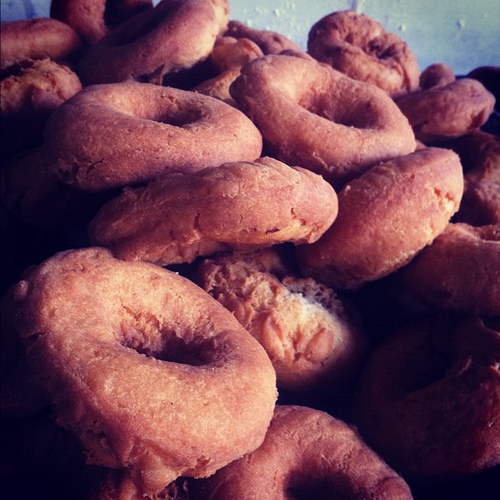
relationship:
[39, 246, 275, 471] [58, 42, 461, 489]
fried donut on pile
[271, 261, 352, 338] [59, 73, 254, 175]
toppings on donut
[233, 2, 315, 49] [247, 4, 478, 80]
donut crumbs on counter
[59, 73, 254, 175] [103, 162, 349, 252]
donut on donut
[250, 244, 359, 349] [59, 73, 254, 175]
frosting on donut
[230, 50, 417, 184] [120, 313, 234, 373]
plain donut with hole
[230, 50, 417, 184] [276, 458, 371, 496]
plain donut with hole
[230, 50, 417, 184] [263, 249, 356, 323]
plain donut with hole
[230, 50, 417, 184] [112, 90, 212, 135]
plain donut with hole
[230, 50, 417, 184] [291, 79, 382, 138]
plain donut with hole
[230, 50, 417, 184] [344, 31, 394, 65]
plain donut with hole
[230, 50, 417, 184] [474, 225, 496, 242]
plain donut with hole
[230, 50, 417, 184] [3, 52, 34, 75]
plain donut with hole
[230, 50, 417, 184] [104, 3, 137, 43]
plain donut with hole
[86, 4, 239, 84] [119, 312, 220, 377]
brown doughnut with hole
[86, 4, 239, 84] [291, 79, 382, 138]
brown doughnut with hole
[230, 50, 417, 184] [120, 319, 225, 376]
plain donut with hole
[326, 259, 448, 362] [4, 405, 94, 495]
shadow next to donut